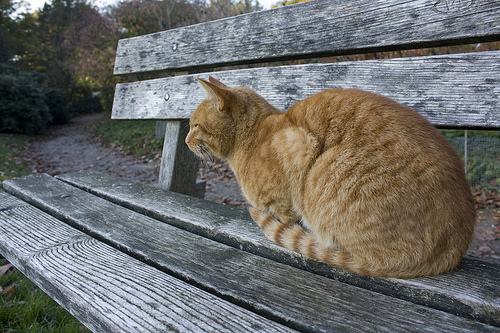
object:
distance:
[0, 0, 91, 172]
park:
[0, 0, 499, 333]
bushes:
[0, 74, 56, 136]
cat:
[182, 75, 474, 277]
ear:
[197, 77, 238, 113]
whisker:
[193, 142, 222, 181]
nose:
[184, 132, 194, 144]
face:
[184, 105, 215, 146]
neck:
[231, 109, 270, 158]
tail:
[247, 204, 418, 279]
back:
[283, 88, 405, 153]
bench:
[0, 0, 495, 333]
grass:
[7, 283, 47, 328]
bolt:
[163, 92, 170, 101]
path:
[38, 119, 109, 172]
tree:
[0, 0, 295, 137]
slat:
[114, 34, 194, 66]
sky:
[27, 1, 45, 14]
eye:
[193, 123, 201, 128]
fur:
[327, 156, 343, 167]